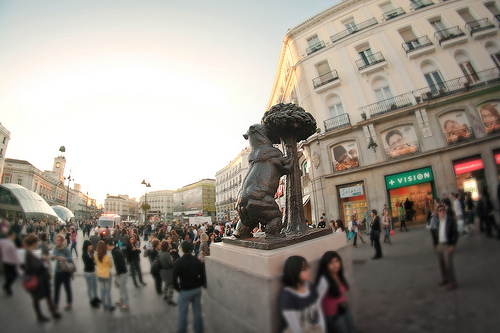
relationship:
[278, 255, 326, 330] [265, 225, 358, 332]
woman leaning against wall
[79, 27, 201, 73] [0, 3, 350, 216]
cloud in sky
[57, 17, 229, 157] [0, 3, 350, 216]
clouds are in sky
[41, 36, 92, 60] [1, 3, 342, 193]
clouds are in sky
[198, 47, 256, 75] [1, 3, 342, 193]
clouds are in sky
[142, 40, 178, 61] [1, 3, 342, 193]
clouds are in sky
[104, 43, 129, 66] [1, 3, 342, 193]
clouds are in sky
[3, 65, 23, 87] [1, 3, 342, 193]
clouds are in sky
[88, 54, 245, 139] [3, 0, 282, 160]
white clouds are in sky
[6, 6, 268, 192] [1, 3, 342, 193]
clouds are in sky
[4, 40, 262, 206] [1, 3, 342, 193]
cloud in sky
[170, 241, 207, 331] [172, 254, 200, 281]
person wearing sweater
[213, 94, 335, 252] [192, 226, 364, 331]
statue on platform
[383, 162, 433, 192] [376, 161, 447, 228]
sign on front of store front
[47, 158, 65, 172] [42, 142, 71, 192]
clock on tower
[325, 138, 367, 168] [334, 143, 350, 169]
portrait has face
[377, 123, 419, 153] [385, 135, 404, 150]
portrait has face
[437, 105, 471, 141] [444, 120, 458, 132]
portrait has face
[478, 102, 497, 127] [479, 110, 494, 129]
portrait has face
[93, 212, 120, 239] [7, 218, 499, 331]
truck on side of walkway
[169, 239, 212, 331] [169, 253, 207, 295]
person wearing black jacket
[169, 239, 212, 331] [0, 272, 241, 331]
person along walkway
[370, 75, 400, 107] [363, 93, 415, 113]
window on front of balcony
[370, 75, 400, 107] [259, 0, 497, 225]
window on front of building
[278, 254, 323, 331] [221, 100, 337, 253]
woman on side of statue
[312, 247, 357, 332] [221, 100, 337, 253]
woman on side of statue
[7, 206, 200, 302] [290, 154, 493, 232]
crowd at marketplace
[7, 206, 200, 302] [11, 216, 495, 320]
crowd on walkway